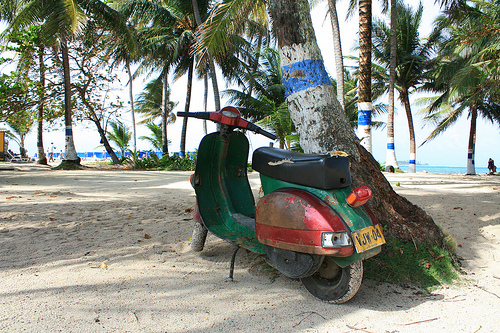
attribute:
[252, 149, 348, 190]
seat — torn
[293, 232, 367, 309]
wheel — black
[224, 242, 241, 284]
center stand — Center 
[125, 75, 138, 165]
tree — white tropical 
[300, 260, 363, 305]
wheel — rubber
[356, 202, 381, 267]
number — Yellow plate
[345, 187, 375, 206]
light — Rear 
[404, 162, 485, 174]
water — blue, far away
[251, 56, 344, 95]
blue stripe — blue 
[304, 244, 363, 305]
tire — rear 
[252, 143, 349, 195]
seat — Black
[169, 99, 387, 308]
bike — red  , green , motorized 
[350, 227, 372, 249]
plate — metal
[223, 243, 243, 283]
kickstand — down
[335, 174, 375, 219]
light — red 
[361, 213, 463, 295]
grass — green , patch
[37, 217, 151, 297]
sand — off white 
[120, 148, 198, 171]
shrub — Green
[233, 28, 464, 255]
tree — blue , brown white 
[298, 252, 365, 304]
wheel — Rear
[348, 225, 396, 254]
liscense plate — black, yellow ,  license  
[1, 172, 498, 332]
sand — white